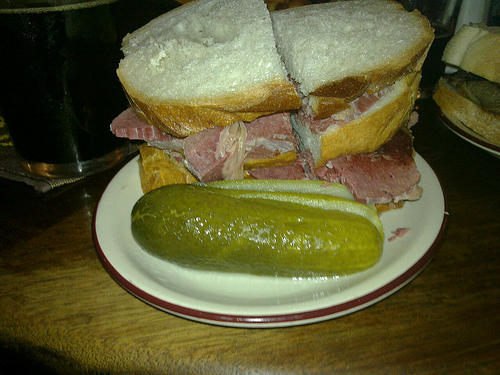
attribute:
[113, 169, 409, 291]
dill pickle — sliced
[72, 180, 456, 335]
plate — white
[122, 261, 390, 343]
stripe — red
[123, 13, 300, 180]
bread — white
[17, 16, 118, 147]
soda — dark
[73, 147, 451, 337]
lunch plate — full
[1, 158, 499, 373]
table — wooden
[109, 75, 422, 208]
meat — ham, pink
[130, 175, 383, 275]
pickle — large, green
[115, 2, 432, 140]
bread — thick, white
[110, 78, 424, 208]
ham — thick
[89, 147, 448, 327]
stripe — maroon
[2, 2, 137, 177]
glass — filled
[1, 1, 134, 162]
drink — dark 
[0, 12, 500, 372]
table — wooden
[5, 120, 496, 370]
desk —  dark-colored 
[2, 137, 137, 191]
tablecloth — small